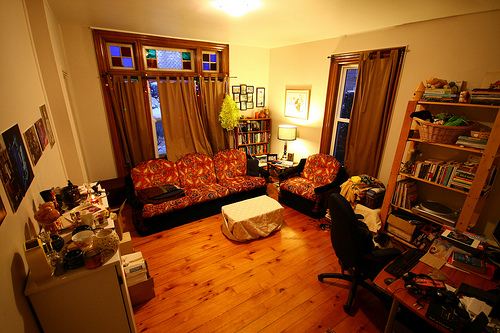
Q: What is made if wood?
A: The book shelf.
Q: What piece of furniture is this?
A: A chair.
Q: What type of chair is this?
A: A swivel chair.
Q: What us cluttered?
A: The set of shelves.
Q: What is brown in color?
A: The floor.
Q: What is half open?
A: The brown curtain.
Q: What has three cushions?
A: The couch.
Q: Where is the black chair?
A: At the desk.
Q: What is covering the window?
A: Curtain.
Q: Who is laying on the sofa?
A: No one.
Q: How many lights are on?
A: Two.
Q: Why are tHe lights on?
A: It's night.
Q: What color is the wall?
A: Beige.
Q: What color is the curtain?
A: Brown.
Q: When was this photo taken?
A: Night.